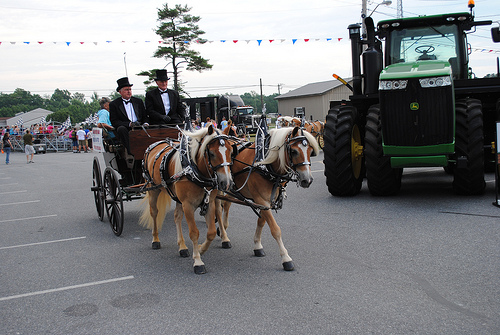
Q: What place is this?
A: It is a parking lot.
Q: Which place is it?
A: It is a parking lot.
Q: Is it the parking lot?
A: Yes, it is the parking lot.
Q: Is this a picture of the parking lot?
A: Yes, it is showing the parking lot.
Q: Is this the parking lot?
A: Yes, it is the parking lot.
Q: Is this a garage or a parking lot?
A: It is a parking lot.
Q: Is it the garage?
A: No, it is the parking lot.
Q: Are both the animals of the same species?
A: Yes, all the animals are horses.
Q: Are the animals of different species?
A: No, all the animals are horses.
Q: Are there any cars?
A: No, there are no cars.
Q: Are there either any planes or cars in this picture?
A: No, there are no cars or planes.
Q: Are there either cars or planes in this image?
A: No, there are no cars or planes.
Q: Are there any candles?
A: No, there are no candles.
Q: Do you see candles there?
A: No, there are no candles.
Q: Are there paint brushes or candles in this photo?
A: No, there are no candles or paint brushes.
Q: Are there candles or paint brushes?
A: No, there are no candles or paint brushes.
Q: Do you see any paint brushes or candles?
A: No, there are no candles or paint brushes.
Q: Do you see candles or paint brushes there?
A: No, there are no candles or paint brushes.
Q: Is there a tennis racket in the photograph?
A: No, there are no rackets.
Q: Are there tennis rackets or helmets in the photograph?
A: No, there are no tennis rackets or helmets.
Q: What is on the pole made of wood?
A: The powerlines are on the pole.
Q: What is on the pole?
A: The powerlines are on the pole.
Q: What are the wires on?
A: The wires are on the pole.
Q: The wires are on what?
A: The wires are on the pole.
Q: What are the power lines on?
A: The wires are on the pole.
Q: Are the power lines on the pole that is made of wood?
A: Yes, the power lines are on the pole.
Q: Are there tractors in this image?
A: Yes, there is a tractor.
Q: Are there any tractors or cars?
A: Yes, there is a tractor.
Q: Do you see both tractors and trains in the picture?
A: No, there is a tractor but no trains.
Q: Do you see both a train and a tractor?
A: No, there is a tractor but no trains.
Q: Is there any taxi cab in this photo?
A: No, there are no taxis.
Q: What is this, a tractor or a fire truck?
A: This is a tractor.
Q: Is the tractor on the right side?
A: Yes, the tractor is on the right of the image.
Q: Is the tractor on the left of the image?
A: No, the tractor is on the right of the image.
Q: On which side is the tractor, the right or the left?
A: The tractor is on the right of the image.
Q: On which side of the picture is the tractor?
A: The tractor is on the right of the image.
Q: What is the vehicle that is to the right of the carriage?
A: The vehicle is a tractor.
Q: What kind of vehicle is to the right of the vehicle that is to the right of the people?
A: The vehicle is a tractor.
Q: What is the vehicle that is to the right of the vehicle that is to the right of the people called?
A: The vehicle is a tractor.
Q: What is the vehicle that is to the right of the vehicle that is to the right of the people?
A: The vehicle is a tractor.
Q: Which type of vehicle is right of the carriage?
A: The vehicle is a tractor.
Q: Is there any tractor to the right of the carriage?
A: Yes, there is a tractor to the right of the carriage.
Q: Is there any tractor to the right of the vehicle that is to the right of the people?
A: Yes, there is a tractor to the right of the carriage.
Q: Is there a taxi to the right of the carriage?
A: No, there is a tractor to the right of the carriage.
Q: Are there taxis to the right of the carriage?
A: No, there is a tractor to the right of the carriage.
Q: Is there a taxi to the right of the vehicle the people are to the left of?
A: No, there is a tractor to the right of the carriage.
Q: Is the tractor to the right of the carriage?
A: Yes, the tractor is to the right of the carriage.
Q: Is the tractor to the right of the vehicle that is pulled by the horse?
A: Yes, the tractor is to the right of the carriage.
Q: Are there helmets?
A: No, there are no helmets.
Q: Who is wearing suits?
A: The man is wearing suits.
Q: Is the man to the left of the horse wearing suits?
A: Yes, the man is wearing suits.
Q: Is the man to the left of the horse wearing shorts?
A: No, the man is wearing suits.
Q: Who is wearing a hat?
A: The man is wearing a hat.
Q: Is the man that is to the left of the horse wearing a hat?
A: Yes, the man is wearing a hat.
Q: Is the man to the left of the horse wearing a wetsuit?
A: No, the man is wearing a hat.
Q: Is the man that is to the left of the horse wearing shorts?
A: No, the man is wearing suits.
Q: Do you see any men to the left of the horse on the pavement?
A: Yes, there is a man to the left of the horse.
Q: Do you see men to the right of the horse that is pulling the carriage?
A: No, the man is to the left of the horse.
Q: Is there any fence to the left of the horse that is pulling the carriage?
A: No, there is a man to the left of the horse.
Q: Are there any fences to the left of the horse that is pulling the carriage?
A: No, there is a man to the left of the horse.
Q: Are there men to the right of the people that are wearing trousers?
A: Yes, there is a man to the right of the people.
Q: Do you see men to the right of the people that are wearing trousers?
A: Yes, there is a man to the right of the people.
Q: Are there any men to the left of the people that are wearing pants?
A: No, the man is to the right of the people.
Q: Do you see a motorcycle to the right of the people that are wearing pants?
A: No, there is a man to the right of the people.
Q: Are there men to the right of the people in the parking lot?
A: Yes, there is a man to the right of the people.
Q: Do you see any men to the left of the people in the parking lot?
A: No, the man is to the right of the people.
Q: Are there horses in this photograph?
A: Yes, there is a horse.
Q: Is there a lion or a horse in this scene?
A: Yes, there is a horse.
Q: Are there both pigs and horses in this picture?
A: No, there is a horse but no pigs.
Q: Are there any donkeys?
A: No, there are no donkeys.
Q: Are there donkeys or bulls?
A: No, there are no donkeys or bulls.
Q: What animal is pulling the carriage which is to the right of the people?
A: The horse is pulling the carriage.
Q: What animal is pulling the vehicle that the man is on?
A: The horse is pulling the carriage.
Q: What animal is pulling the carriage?
A: The horse is pulling the carriage.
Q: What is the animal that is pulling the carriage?
A: The animal is a horse.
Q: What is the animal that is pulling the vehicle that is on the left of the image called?
A: The animal is a horse.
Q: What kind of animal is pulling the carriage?
A: The animal is a horse.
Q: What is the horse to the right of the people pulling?
A: The horse is pulling the carriage.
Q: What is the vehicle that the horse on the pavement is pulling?
A: The vehicle is a carriage.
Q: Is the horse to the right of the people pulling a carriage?
A: Yes, the horse is pulling a carriage.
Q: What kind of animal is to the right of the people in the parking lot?
A: The animal is a horse.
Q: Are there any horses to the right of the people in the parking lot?
A: Yes, there is a horse to the right of the people.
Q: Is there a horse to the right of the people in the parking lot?
A: Yes, there is a horse to the right of the people.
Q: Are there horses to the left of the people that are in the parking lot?
A: No, the horse is to the right of the people.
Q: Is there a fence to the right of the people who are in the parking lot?
A: No, there is a horse to the right of the people.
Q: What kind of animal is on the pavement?
A: The animal is a horse.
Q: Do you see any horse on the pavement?
A: Yes, there is a horse on the pavement.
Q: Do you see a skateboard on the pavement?
A: No, there is a horse on the pavement.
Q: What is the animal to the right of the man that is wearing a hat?
A: The animal is a horse.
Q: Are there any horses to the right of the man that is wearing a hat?
A: Yes, there is a horse to the right of the man.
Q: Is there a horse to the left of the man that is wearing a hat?
A: No, the horse is to the right of the man.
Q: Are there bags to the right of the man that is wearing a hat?
A: No, there is a horse to the right of the man.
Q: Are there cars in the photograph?
A: No, there are no cars.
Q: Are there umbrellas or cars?
A: No, there are no cars or umbrellas.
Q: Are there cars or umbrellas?
A: No, there are no cars or umbrellas.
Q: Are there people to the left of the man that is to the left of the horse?
A: Yes, there are people to the left of the man.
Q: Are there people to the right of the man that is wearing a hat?
A: No, the people are to the left of the man.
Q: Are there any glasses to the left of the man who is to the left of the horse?
A: No, there are people to the left of the man.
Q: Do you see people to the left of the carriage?
A: Yes, there are people to the left of the carriage.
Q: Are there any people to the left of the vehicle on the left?
A: Yes, there are people to the left of the carriage.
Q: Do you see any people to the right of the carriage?
A: No, the people are to the left of the carriage.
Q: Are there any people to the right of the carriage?
A: No, the people are to the left of the carriage.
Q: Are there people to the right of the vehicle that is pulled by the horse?
A: No, the people are to the left of the carriage.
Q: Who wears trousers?
A: The people wear trousers.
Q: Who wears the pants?
A: The people wear trousers.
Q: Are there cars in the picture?
A: No, there are no cars.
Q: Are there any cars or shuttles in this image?
A: No, there are no cars or shuttles.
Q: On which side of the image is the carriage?
A: The carriage is on the left of the image.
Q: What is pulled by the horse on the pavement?
A: The carriage is pulled by the horse.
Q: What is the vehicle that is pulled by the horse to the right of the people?
A: The vehicle is a carriage.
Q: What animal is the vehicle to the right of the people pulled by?
A: The carriage is pulled by the horse.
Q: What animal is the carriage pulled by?
A: The carriage is pulled by the horse.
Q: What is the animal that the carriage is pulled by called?
A: The animal is a horse.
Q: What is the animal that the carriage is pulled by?
A: The animal is a horse.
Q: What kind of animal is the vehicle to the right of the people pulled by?
A: The carriage is pulled by the horse.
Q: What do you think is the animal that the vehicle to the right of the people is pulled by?
A: The animal is a horse.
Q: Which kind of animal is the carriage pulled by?
A: The carriage is pulled by the horse.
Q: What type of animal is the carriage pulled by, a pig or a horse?
A: The carriage is pulled by a horse.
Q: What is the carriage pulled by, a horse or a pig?
A: The carriage is pulled by a horse.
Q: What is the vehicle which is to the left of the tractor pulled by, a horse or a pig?
A: The carriage is pulled by a horse.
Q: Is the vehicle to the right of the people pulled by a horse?
A: Yes, the carriage is pulled by a horse.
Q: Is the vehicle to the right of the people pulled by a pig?
A: No, the carriage is pulled by a horse.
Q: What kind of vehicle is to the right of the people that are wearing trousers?
A: The vehicle is a carriage.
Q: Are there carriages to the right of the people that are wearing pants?
A: Yes, there is a carriage to the right of the people.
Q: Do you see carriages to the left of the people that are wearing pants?
A: No, the carriage is to the right of the people.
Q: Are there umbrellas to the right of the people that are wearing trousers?
A: No, there is a carriage to the right of the people.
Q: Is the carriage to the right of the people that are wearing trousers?
A: Yes, the carriage is to the right of the people.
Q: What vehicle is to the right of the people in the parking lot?
A: The vehicle is a carriage.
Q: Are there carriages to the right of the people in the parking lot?
A: Yes, there is a carriage to the right of the people.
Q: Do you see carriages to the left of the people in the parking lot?
A: No, the carriage is to the right of the people.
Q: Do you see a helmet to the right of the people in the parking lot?
A: No, there is a carriage to the right of the people.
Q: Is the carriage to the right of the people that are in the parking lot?
A: Yes, the carriage is to the right of the people.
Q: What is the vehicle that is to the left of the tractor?
A: The vehicle is a carriage.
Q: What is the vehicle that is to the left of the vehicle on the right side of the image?
A: The vehicle is a carriage.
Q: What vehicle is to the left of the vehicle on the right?
A: The vehicle is a carriage.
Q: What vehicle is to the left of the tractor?
A: The vehicle is a carriage.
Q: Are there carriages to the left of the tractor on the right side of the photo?
A: Yes, there is a carriage to the left of the tractor.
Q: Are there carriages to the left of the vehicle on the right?
A: Yes, there is a carriage to the left of the tractor.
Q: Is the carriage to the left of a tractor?
A: Yes, the carriage is to the left of a tractor.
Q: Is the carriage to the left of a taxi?
A: No, the carriage is to the left of a tractor.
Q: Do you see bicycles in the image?
A: No, there are no bicycles.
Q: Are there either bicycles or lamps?
A: No, there are no bicycles or lamps.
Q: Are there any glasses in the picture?
A: No, there are no glasses.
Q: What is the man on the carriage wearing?
A: The man is wearing suits.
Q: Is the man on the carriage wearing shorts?
A: No, the man is wearing suits.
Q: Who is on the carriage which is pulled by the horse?
A: The man is on the carriage.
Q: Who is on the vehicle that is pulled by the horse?
A: The man is on the carriage.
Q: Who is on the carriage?
A: The man is on the carriage.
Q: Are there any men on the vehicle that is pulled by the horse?
A: Yes, there is a man on the carriage.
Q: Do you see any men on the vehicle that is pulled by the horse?
A: Yes, there is a man on the carriage.